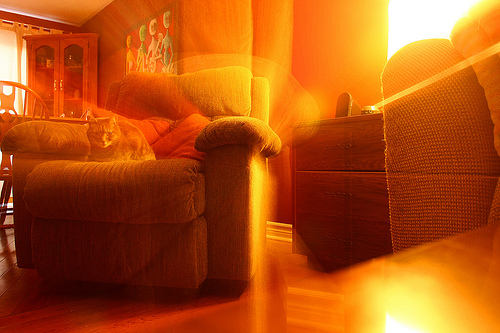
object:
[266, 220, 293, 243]
baseboard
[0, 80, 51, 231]
chair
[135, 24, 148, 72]
alien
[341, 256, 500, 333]
light reflection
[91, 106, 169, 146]
pillow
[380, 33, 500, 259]
arm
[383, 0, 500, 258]
chair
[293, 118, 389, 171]
drawer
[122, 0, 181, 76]
art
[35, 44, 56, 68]
glass panes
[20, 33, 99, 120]
cabinet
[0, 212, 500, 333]
floor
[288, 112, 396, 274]
cabinet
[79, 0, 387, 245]
wall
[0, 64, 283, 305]
chair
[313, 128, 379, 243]
wooden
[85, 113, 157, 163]
cat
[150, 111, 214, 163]
pillow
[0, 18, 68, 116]
curtain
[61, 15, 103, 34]
corner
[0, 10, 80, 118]
wall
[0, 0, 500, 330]
room